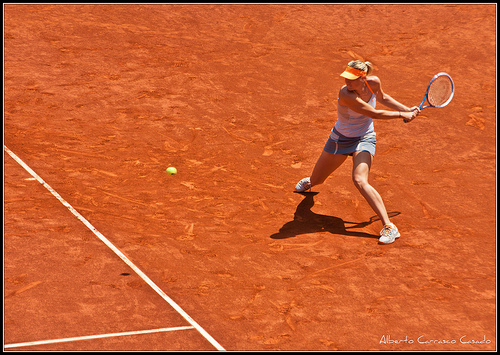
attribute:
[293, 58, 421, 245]
player — tennis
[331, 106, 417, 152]
shirt — white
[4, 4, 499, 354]
tennis court — orange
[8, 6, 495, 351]
turf — orange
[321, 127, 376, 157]
shorts — grey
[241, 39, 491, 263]
player — tennis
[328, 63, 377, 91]
visor — orange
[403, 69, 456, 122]
racket — tennis